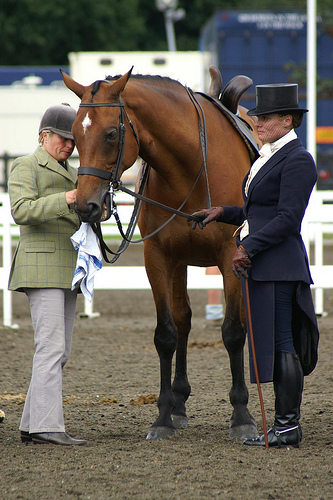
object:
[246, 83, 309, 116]
top hat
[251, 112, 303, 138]
head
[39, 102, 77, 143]
riding cap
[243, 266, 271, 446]
cane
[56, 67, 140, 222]
head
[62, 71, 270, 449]
horse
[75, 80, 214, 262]
bridle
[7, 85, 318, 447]
people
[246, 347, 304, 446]
shoes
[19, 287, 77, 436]
pants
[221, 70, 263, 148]
saddle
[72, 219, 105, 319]
towel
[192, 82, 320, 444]
woman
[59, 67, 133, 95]
ears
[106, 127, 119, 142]
left eye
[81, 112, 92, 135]
spot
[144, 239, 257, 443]
legs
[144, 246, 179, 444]
right leg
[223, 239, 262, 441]
left leg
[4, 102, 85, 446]
woman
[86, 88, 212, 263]
reins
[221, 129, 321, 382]
suit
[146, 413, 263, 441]
hooves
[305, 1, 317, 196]
pole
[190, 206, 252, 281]
gloves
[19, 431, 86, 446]
boots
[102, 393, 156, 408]
dung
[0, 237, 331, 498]
ground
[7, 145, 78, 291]
jacket